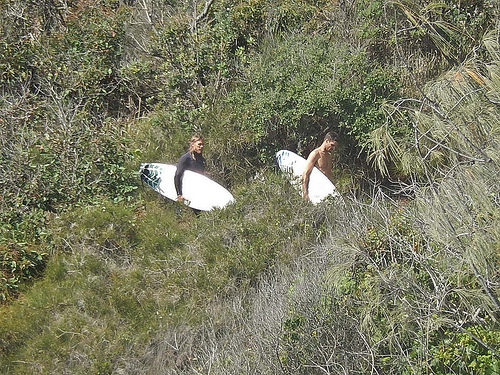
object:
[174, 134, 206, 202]
man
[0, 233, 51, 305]
bushes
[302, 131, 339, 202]
man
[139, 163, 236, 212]
surfboard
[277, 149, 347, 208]
surfboard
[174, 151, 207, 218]
wetsuit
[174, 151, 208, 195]
shirt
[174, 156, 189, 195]
arm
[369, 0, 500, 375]
right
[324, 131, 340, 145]
short hair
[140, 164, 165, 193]
pattern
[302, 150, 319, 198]
arm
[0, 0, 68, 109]
trees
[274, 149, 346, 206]
board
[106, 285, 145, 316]
grass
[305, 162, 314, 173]
bicep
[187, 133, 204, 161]
hair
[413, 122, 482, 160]
branches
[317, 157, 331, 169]
chest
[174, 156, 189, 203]
right